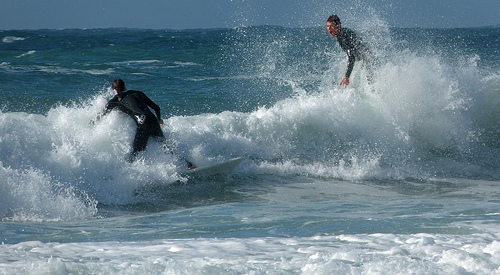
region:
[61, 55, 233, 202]
man in the ocean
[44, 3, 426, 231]
two people in the ocean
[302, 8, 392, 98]
man surfing in the ocean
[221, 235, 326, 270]
white water in the ocean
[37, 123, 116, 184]
white wave in the ocean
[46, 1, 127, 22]
sky above the ocean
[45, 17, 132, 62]
water in the background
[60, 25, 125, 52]
calm water in the distance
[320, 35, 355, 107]
arm of the person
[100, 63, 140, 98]
head of the surfer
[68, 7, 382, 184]
two surfers on same wave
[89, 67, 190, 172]
black wetsuit of surfer with back to camera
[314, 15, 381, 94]
surfer with face visible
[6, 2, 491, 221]
white spray of wave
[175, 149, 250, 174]
white surfboard sticking of wave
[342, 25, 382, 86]
black wetsuit of surfer with face visible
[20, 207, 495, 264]
white foamy water in front of wave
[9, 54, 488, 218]
wave crashing back into ocean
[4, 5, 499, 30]
blue skyline above ocean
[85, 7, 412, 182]
surfers riding a wave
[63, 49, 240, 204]
person in the ocean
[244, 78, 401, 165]
white wave in the water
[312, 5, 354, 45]
head of the person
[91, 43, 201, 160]
person wearing a wetsuit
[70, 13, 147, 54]
water in the background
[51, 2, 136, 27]
sky above the water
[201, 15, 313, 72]
splash of water in the air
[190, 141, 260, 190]
white board in water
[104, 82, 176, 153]
black wetsuit on man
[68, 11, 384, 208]
two surfers in the ocean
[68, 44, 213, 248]
surfer in the ocean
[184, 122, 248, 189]
board in the water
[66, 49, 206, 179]
man wearing a wetsuit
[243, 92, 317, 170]
wave forming in water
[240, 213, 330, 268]
water in the foreground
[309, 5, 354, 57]
head of the man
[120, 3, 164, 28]
sky in the background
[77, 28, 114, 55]
still water in the distance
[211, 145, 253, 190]
front of the board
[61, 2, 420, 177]
Two guys going out to catch some waves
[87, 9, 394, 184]
Two surfers talking over the waves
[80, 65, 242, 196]
Surfers wet suit is black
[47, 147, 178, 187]
The wave is spraying white droplets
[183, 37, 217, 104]
The ocean is a beautiful blue green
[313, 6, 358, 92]
This surfer is yelling over the waves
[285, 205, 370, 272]
Foam from the waves settling on the shore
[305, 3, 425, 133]
He is riding a wave or very tall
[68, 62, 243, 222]
This surfer is on a surfboard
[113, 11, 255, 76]
The water is very rough today